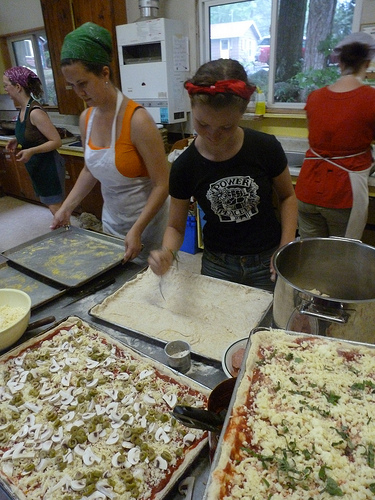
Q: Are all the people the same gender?
A: Yes, all the people are female.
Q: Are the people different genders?
A: No, all the people are female.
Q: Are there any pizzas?
A: Yes, there is a pizza.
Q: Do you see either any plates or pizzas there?
A: Yes, there is a pizza.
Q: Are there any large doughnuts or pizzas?
A: Yes, there is a large pizza.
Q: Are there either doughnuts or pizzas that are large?
A: Yes, the pizza is large.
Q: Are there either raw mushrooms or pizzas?
A: Yes, there is a raw pizza.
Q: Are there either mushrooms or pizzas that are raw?
A: Yes, the pizza is raw.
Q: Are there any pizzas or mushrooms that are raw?
A: Yes, the pizza is raw.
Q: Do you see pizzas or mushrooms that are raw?
A: Yes, the pizza is raw.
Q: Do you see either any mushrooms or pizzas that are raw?
A: Yes, the pizza is raw.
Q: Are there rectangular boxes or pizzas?
A: Yes, there is a rectangular pizza.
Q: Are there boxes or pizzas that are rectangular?
A: Yes, the pizza is rectangular.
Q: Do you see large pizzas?
A: Yes, there is a large pizza.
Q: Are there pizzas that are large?
A: Yes, there is a pizza that is large.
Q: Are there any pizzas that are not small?
A: Yes, there is a large pizza.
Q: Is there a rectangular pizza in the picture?
A: Yes, there is a rectangular pizza.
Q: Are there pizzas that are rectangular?
A: Yes, there is a pizza that is rectangular.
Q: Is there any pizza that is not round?
A: Yes, there is a rectangular pizza.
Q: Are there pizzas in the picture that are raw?
A: Yes, there is a pizza that is raw.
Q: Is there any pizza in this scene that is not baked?
A: Yes, there is a raw pizza.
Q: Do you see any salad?
A: No, there is no salad.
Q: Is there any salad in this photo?
A: No, there is no salad.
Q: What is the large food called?
A: The food is a pizza.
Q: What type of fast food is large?
A: The fast food is a pizza.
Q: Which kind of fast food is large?
A: The fast food is a pizza.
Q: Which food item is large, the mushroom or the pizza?
A: The pizza is large.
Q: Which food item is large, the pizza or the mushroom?
A: The pizza is large.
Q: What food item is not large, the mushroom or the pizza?
A: The mushroom is not large.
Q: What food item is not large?
A: The food item is a mushroom.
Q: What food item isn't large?
A: The food item is a mushroom.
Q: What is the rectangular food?
A: The food is a pizza.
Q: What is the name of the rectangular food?
A: The food is a pizza.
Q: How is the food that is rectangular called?
A: The food is a pizza.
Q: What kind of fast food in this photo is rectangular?
A: The fast food is a pizza.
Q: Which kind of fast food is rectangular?
A: The fast food is a pizza.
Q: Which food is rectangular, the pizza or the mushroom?
A: The pizza is rectangular.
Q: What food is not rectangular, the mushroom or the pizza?
A: The mushroom is not rectangular.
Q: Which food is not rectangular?
A: The food is a mushroom.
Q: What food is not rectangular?
A: The food is a mushroom.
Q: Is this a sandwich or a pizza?
A: This is a pizza.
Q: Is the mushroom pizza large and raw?
A: Yes, the pizza is large and raw.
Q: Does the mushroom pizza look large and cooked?
A: No, the pizza is large but raw.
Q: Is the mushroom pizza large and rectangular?
A: Yes, the pizza is large and rectangular.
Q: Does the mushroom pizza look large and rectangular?
A: Yes, the pizza is large and rectangular.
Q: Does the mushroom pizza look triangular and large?
A: No, the pizza is large but rectangular.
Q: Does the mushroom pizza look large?
A: Yes, the pizza is large.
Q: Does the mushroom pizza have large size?
A: Yes, the pizza is large.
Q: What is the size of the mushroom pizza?
A: The pizza is large.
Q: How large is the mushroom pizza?
A: The pizza is large.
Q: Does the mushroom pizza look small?
A: No, the pizza is large.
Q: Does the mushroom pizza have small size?
A: No, the pizza is large.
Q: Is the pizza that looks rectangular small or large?
A: The pizza is large.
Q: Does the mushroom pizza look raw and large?
A: Yes, the pizza is raw and large.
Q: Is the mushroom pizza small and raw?
A: No, the pizza is raw but large.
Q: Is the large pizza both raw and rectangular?
A: Yes, the pizza is raw and rectangular.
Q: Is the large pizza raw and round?
A: No, the pizza is raw but rectangular.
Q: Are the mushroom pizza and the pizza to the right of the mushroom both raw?
A: Yes, both the pizza and the pizza are raw.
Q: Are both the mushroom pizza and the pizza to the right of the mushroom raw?
A: Yes, both the pizza and the pizza are raw.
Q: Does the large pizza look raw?
A: Yes, the pizza is raw.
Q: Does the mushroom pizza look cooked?
A: No, the pizza is raw.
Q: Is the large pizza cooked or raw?
A: The pizza is raw.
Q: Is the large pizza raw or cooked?
A: The pizza is raw.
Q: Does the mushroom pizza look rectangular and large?
A: Yes, the pizza is rectangular and large.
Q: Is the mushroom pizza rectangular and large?
A: Yes, the pizza is rectangular and large.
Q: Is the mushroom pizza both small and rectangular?
A: No, the pizza is rectangular but large.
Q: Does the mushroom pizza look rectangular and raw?
A: Yes, the pizza is rectangular and raw.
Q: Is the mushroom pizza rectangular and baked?
A: No, the pizza is rectangular but raw.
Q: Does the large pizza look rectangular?
A: Yes, the pizza is rectangular.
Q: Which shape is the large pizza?
A: The pizza is rectangular.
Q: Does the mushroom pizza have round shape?
A: No, the pizza is rectangular.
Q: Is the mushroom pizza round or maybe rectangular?
A: The pizza is rectangular.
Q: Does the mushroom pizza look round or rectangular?
A: The pizza is rectangular.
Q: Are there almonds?
A: No, there are no almonds.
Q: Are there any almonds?
A: No, there are no almonds.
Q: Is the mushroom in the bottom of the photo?
A: Yes, the mushroom is in the bottom of the image.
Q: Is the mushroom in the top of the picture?
A: No, the mushroom is in the bottom of the image.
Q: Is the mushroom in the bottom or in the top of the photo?
A: The mushroom is in the bottom of the image.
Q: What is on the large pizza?
A: The mushroom is on the pizza.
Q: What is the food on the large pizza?
A: The food is a mushroom.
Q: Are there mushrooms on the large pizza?
A: Yes, there is a mushroom on the pizza.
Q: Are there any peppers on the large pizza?
A: No, there is a mushroom on the pizza.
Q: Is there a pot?
A: Yes, there is a pot.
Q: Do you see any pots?
A: Yes, there is a pot.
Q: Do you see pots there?
A: Yes, there is a pot.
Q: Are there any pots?
A: Yes, there is a pot.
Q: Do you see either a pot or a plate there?
A: Yes, there is a pot.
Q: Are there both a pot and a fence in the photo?
A: No, there is a pot but no fences.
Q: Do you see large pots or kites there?
A: Yes, there is a large pot.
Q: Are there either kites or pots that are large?
A: Yes, the pot is large.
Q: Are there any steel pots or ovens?
A: Yes, there is a steel pot.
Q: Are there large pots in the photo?
A: Yes, there is a large pot.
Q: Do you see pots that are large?
A: Yes, there is a pot that is large.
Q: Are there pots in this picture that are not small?
A: Yes, there is a large pot.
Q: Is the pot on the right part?
A: Yes, the pot is on the right of the image.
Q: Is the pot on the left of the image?
A: No, the pot is on the right of the image.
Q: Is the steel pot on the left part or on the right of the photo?
A: The pot is on the right of the image.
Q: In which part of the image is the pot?
A: The pot is on the right of the image.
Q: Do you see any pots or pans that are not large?
A: No, there is a pot but it is large.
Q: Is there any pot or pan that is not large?
A: No, there is a pot but it is large.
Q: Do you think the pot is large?
A: Yes, the pot is large.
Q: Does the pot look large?
A: Yes, the pot is large.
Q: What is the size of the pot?
A: The pot is large.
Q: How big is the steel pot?
A: The pot is large.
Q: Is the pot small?
A: No, the pot is large.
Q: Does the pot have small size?
A: No, the pot is large.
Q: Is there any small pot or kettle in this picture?
A: No, there is a pot but it is large.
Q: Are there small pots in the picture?
A: No, there is a pot but it is large.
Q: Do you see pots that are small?
A: No, there is a pot but it is large.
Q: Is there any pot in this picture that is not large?
A: No, there is a pot but it is large.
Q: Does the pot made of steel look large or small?
A: The pot is large.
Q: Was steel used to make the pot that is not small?
A: Yes, the pot is made of steel.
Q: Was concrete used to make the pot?
A: No, the pot is made of steel.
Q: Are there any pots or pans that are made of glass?
A: No, there is a pot but it is made of steel.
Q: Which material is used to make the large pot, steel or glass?
A: The pot is made of steel.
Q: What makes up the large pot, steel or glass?
A: The pot is made of steel.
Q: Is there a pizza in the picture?
A: Yes, there is a pizza.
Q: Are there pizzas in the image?
A: Yes, there is a pizza.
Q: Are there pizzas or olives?
A: Yes, there is a pizza.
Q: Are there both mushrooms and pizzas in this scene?
A: Yes, there are both a pizza and mushrooms.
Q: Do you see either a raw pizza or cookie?
A: Yes, there is a raw pizza.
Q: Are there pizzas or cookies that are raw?
A: Yes, the pizza is raw.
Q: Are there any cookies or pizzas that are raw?
A: Yes, the pizza is raw.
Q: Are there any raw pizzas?
A: Yes, there is a raw pizza.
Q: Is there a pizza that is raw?
A: Yes, there is a pizza that is raw.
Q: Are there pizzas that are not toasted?
A: Yes, there is a raw pizza.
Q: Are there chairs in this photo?
A: No, there are no chairs.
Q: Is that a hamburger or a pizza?
A: That is a pizza.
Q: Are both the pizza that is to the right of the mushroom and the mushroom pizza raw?
A: Yes, both the pizza and the pizza are raw.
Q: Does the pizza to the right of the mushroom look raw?
A: Yes, the pizza is raw.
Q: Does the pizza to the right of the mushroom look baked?
A: No, the pizza is raw.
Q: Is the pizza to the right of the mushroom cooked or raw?
A: The pizza is raw.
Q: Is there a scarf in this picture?
A: Yes, there is a scarf.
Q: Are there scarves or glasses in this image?
A: Yes, there is a scarf.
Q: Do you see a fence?
A: No, there are no fences.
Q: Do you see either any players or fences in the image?
A: No, there are no fences or players.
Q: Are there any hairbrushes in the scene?
A: No, there are no hairbrushes.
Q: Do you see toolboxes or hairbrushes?
A: No, there are no hairbrushes or toolboxes.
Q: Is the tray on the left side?
A: Yes, the tray is on the left of the image.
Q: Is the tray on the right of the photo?
A: No, the tray is on the left of the image.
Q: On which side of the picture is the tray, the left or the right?
A: The tray is on the left of the image.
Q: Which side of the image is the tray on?
A: The tray is on the left of the image.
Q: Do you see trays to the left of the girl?
A: Yes, there is a tray to the left of the girl.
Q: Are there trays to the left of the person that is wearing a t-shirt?
A: Yes, there is a tray to the left of the girl.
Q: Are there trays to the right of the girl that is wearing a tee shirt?
A: No, the tray is to the left of the girl.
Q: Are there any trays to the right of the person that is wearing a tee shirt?
A: No, the tray is to the left of the girl.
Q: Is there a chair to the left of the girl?
A: No, there is a tray to the left of the girl.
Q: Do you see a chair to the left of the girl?
A: No, there is a tray to the left of the girl.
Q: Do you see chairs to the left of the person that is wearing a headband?
A: No, there is a tray to the left of the girl.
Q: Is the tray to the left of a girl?
A: Yes, the tray is to the left of a girl.